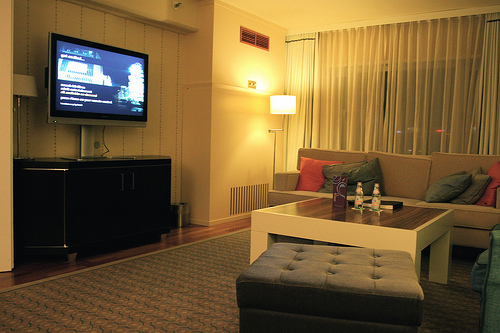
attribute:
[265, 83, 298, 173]
lamp —  odd, for  floor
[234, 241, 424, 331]
foot rest —  grey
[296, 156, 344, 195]
pink pillow —  small,  pink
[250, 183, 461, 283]
table — for coffee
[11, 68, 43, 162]
desk lamp —  tall, for desk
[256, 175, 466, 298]
table —  white ,  with wood top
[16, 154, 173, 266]
stand —  black, for entertainment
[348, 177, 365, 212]
bottled drink —  bottled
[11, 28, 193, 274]
entertainment center —  black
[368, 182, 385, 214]
water —  bottled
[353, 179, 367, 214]
water —  bottled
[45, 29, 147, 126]
television — on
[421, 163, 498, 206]
pillows —  three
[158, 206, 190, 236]
trashcan —  small,  metal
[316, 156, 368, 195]
pillow —  small,  grey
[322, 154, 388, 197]
pillow —   small,  blue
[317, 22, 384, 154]
surtain —  sheer,  White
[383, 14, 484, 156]
surtain —  sheer,  White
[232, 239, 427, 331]
ottoman —  dark colored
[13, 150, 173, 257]
cabinet —  black,  glass topped 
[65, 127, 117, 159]
stand —  silver